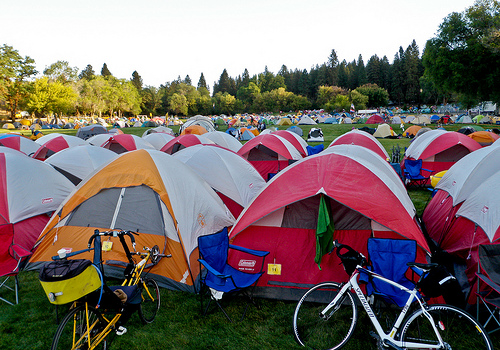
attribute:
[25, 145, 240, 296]
tent — orange, white, gray, light colored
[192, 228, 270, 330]
folding chair — blue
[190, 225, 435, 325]
two folding chairs — blue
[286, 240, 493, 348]
bicycle — white, light colored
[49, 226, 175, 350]
reclining bicycle — yellow, black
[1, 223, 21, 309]
folding chair — red, grey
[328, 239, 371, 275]
handlebars — black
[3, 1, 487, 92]
sky — gray, hazy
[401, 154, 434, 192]
chair — blue, black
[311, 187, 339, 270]
towel — green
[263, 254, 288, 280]
tag — yellow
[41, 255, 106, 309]
storage container — yellow, black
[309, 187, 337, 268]
shirt — green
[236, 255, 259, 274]
decal — white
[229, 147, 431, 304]
tent — red, white